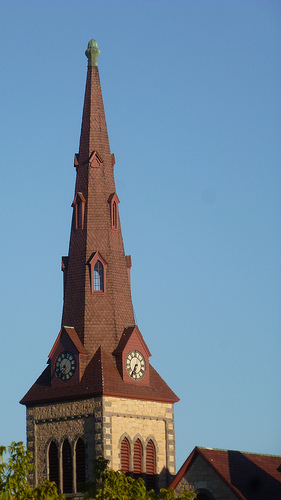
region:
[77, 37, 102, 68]
gray tip of clock tower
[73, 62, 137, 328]
brown steeple of clock tower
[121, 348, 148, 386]
black and white clock in clock tower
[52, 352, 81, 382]
black and white clock in clock tower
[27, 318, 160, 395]
clocks with roman numerals in clock tower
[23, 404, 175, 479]
tan and brown clock tower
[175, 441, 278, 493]
brown roof of building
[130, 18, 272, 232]
blue cloudless sky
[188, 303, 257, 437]
blue cloudless sky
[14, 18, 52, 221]
blue cloudless sky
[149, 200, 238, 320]
Sky is blue color.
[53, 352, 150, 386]
Two clocks on tower.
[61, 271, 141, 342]
Tower is red color.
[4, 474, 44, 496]
Leaves are green color.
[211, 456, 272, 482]
Roof is red color.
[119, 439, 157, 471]
Shutters are red color.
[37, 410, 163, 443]
Wall is brown color.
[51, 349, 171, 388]
5.35 is the time shown.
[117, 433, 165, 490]
Windows are attached to the wall.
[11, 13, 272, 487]
Day time picture.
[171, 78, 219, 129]
part of the sky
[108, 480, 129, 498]
part of some green plant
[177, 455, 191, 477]
edge of a roof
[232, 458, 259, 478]
part of a shade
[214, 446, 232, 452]
tip of the roof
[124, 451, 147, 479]
part of a window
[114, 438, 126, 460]
edge of a window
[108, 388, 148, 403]
edge of a roof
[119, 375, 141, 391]
edge of a clock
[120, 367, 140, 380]
part of a clock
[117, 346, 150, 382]
black and white clock with roman numerals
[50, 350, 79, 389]
black and white clock with roman numerals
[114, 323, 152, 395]
clock in brown clock tower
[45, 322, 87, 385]
clock in brown clock tower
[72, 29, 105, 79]
blue top of clock tower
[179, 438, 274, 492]
brown roof of old building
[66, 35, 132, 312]
brown steeple of old building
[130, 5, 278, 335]
clear blue sky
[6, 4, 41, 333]
clear blue sky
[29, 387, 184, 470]
tan and brown tower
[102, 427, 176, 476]
red vents on the side of the building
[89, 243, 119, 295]
window on the top of the building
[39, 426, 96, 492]
three vents on the side of the building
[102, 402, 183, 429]
brick wall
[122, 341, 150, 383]
black and white clock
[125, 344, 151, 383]
roman numerals in black writing on the clock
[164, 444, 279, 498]
red roof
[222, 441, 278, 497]
shadow on the roof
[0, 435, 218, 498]
green leaves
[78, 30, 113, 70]
copper tip of the building